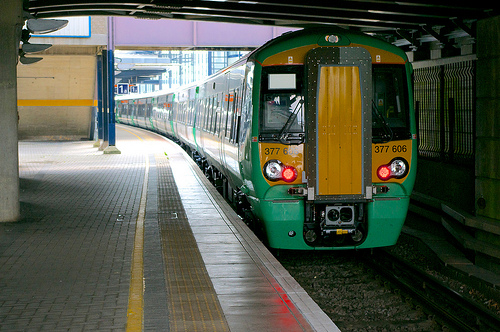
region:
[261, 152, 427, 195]
headlights on a subway train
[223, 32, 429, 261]
yellow and pale green subway train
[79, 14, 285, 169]
subway train station with blue poles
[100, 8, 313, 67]
purple overpass seen from subway station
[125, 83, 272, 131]
subway bus windows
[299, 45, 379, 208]
yellow door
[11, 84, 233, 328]
loading and unloading passenger zone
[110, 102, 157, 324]
yellow line showing where to halt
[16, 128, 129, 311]
brick walkway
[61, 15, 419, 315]
subway train pulling into the station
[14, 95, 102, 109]
Yellow line on wall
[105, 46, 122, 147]
Blue pole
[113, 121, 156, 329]
Yellow painted line on the ground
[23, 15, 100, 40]
White and blue sign on the wall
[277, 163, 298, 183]
Red light on the trains front left side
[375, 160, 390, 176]
Red light on the trains front right side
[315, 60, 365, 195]
Yellow door on the train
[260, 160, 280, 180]
Black and silver light on left front side of train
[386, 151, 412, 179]
Silver and black light on the right front side of train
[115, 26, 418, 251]
Green, yellow, and black train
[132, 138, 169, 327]
yellow stripe on a train platform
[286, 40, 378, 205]
yellow door on a train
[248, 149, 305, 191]
headlights on a train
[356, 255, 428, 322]
railroad track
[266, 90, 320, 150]
windshield wiper on a window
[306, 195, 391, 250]
train car connector assembly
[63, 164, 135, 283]
bricks on the floor of train platform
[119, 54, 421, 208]
a green and yellow colored train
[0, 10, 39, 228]
a cement pillar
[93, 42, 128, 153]
a blue metal support column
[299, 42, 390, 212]
the yellow door of a subway train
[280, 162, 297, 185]
a red light on the train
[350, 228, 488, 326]
the steel beams of a track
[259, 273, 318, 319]
red light reflecting on the ground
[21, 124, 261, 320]
the passenger loading zone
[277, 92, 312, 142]
the wiper blade of a train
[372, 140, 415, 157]
the numbers 377 606 written in black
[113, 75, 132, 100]
a blue and white sign with the number one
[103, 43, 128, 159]
a blue support post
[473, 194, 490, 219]
a hole in the concrete wall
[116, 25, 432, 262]
Green and yellow train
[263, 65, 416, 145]
Front windows of train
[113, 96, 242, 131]
Side windows of train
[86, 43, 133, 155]
Blue poles holding a bridge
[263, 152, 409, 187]
Front lights of train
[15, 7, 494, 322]
Train in a train station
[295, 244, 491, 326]
Train rails in the soil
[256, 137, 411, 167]
Numbers written in front of train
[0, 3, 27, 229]
column of concrete in train station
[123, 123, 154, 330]
Yellow line in side walk